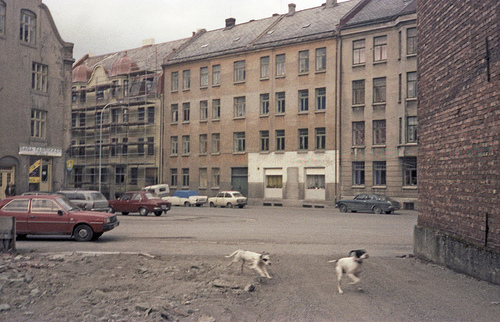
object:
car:
[53, 189, 111, 215]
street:
[0, 205, 500, 322]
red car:
[106, 191, 172, 216]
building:
[161, 0, 420, 211]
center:
[213, 212, 306, 237]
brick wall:
[412, 0, 500, 286]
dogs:
[326, 247, 368, 295]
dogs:
[224, 247, 273, 278]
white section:
[306, 167, 325, 174]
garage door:
[263, 169, 282, 197]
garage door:
[304, 167, 326, 201]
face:
[356, 249, 368, 258]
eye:
[260, 257, 268, 261]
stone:
[50, 254, 67, 262]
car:
[0, 193, 120, 241]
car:
[156, 189, 206, 206]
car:
[207, 189, 245, 209]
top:
[170, 188, 198, 196]